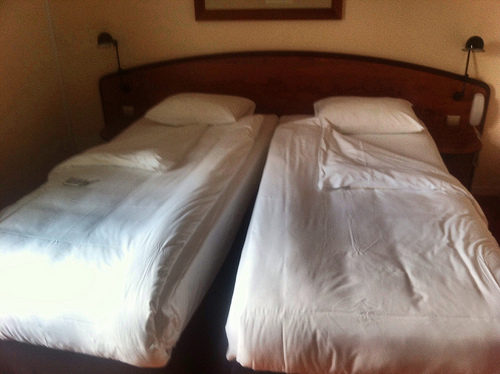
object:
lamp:
[93, 33, 129, 95]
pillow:
[313, 96, 423, 135]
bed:
[0, 113, 277, 369]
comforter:
[40, 123, 212, 181]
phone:
[466, 91, 484, 129]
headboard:
[99, 49, 489, 123]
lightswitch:
[443, 113, 463, 128]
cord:
[470, 123, 499, 158]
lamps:
[450, 37, 483, 101]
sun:
[0, 228, 153, 336]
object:
[56, 171, 91, 188]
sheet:
[341, 130, 449, 175]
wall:
[0, 0, 80, 212]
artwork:
[193, 0, 341, 20]